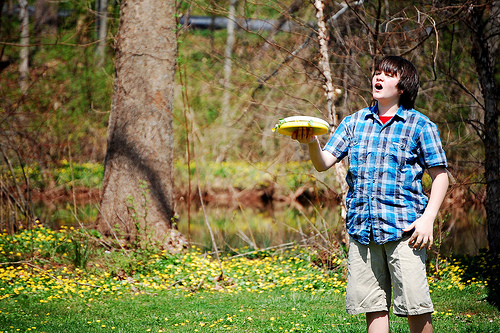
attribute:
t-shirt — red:
[376, 116, 392, 123]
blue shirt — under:
[322, 107, 447, 243]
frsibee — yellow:
[268, 103, 345, 134]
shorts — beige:
[348, 236, 433, 318]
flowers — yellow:
[4, 221, 62, 253]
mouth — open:
[370, 79, 384, 92]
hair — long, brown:
[371, 51, 421, 111]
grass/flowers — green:
[1, 256, 290, 331]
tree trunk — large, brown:
[100, 7, 175, 238]